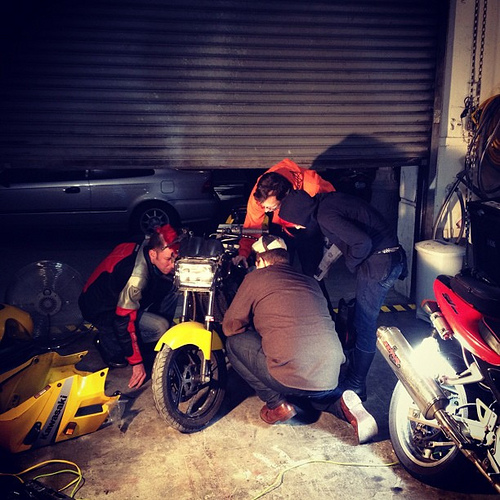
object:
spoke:
[171, 361, 183, 379]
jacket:
[278, 188, 400, 273]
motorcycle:
[375, 271, 499, 490]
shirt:
[221, 263, 347, 390]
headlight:
[176, 261, 216, 287]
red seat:
[430, 272, 494, 356]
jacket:
[77, 238, 152, 365]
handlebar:
[239, 227, 270, 234]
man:
[232, 158, 337, 328]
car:
[0, 168, 223, 243]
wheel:
[385, 348, 479, 477]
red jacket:
[238, 157, 337, 259]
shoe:
[259, 402, 298, 424]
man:
[277, 185, 404, 401]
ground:
[0, 260, 499, 498]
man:
[77, 222, 181, 389]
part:
[0, 349, 121, 453]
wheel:
[152, 320, 228, 433]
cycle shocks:
[204, 291, 214, 330]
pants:
[225, 328, 350, 423]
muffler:
[374, 325, 450, 420]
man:
[221, 232, 379, 442]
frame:
[153, 320, 225, 360]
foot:
[260, 401, 297, 424]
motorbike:
[150, 213, 272, 434]